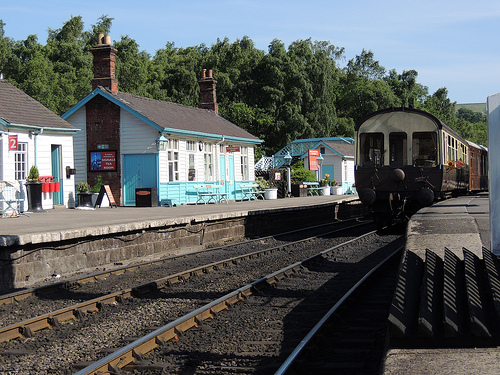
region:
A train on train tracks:
[2, 104, 485, 373]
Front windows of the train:
[356, 128, 441, 170]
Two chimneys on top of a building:
[86, 29, 220, 115]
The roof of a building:
[1, 72, 81, 134]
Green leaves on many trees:
[1, 11, 487, 163]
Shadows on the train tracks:
[29, 198, 406, 373]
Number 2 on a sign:
[5, 130, 19, 155]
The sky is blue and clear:
[1, 1, 498, 103]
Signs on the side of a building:
[81, 139, 123, 175]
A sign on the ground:
[91, 178, 119, 212]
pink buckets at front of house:
[27, 170, 80, 192]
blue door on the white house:
[33, 142, 68, 198]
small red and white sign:
[91, 180, 117, 212]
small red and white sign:
[5, 130, 27, 151]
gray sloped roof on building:
[187, 112, 223, 129]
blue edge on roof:
[163, 122, 259, 144]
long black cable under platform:
[46, 215, 249, 238]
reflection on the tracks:
[337, 242, 467, 317]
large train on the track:
[338, 98, 460, 224]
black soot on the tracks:
[65, 307, 106, 318]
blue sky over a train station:
[2, 0, 495, 46]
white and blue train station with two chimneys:
[57, 34, 266, 204]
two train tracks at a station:
[0, 255, 376, 367]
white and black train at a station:
[355, 107, 490, 221]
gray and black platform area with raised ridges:
[389, 192, 494, 372]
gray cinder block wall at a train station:
[9, 205, 360, 289]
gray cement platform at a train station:
[4, 192, 357, 245]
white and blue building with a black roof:
[0, 76, 83, 216]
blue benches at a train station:
[182, 181, 272, 205]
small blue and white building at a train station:
[313, 139, 356, 194]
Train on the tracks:
[340, 105, 475, 241]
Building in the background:
[272, 131, 363, 196]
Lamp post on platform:
[279, 151, 299, 199]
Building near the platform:
[67, 28, 279, 215]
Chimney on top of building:
[191, 61, 228, 121]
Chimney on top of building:
[89, 33, 134, 100]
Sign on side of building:
[83, 146, 125, 178]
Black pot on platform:
[24, 177, 49, 217]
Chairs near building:
[193, 182, 225, 202]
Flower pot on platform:
[262, 177, 282, 200]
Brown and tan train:
[341, 89, 499, 257]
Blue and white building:
[66, 77, 266, 232]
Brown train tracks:
[7, 213, 389, 374]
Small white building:
[0, 66, 90, 221]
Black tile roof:
[57, 64, 267, 149]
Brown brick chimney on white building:
[69, 36, 136, 223]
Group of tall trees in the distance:
[5, 8, 482, 195]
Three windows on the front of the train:
[355, 131, 452, 182]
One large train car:
[347, 103, 485, 219]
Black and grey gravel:
[0, 206, 427, 373]